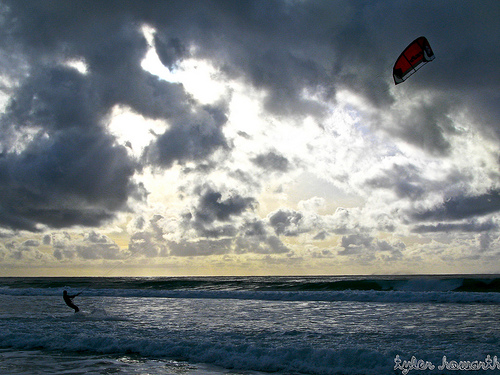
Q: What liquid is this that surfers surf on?
A: Water.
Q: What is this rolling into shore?
A: Waves.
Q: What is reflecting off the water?
A: Sun.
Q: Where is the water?
A: In the ocean.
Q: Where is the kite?
A: In the sky.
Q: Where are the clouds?
A: In the sky.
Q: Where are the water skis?
A: On the man.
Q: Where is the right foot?
A: In the water.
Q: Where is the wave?
A: In the water.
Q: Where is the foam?
A: In the water.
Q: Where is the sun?
A: Behind the clouds.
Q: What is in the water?
A: A man.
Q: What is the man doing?
A: Wind surfing.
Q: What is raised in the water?
A: Waves.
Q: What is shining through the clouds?
A: The sun.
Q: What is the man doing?
A: Parasailing.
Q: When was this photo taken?
A: At sunset.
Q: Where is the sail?
A: In the sky.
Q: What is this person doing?
A: Water skiing.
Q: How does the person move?
A: The sail pulls them.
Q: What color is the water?
A: Blue.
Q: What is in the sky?
A: Clouds.